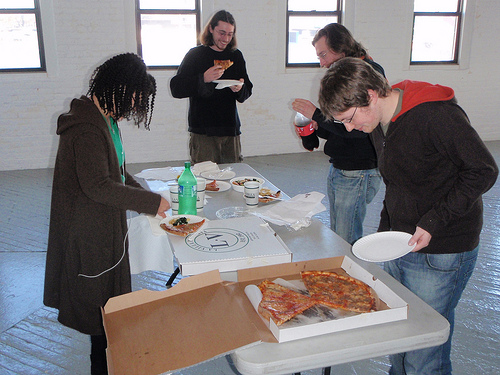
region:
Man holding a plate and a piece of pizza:
[173, 7, 253, 163]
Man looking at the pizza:
[318, 57, 497, 372]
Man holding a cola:
[291, 17, 384, 243]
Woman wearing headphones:
[42, 49, 171, 372]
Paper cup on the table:
[243, 182, 261, 207]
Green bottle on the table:
[177, 160, 198, 215]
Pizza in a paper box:
[256, 269, 376, 326]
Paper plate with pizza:
[161, 215, 205, 235]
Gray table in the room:
[145, 157, 450, 372]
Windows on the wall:
[2, 0, 462, 70]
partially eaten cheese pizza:
[253, 267, 383, 328]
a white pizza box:
[92, 242, 424, 368]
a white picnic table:
[124, 146, 459, 373]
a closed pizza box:
[160, 202, 296, 280]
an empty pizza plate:
[337, 209, 439, 292]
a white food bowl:
[221, 161, 270, 198]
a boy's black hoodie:
[359, 75, 499, 264]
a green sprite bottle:
[176, 152, 215, 234]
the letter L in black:
[207, 235, 234, 252]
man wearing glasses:
[315, 53, 395, 140]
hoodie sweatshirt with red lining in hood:
[376, 75, 498, 260]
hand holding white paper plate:
[348, 218, 438, 269]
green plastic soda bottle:
[172, 156, 201, 224]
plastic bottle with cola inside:
[289, 96, 324, 157]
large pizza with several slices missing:
[187, 250, 416, 365]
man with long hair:
[169, 8, 259, 137]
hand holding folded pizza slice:
[197, 51, 234, 85]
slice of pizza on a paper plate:
[150, 205, 213, 244]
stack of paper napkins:
[192, 159, 221, 178]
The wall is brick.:
[1, 0, 491, 141]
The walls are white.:
[2, 7, 497, 158]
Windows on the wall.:
[1, 2, 487, 76]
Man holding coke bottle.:
[287, 88, 319, 150]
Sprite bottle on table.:
[168, 154, 201, 224]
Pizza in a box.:
[228, 250, 403, 332]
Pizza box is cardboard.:
[90, 252, 409, 374]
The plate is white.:
[350, 223, 417, 265]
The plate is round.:
[350, 221, 422, 266]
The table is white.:
[131, 147, 478, 369]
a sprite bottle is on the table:
[155, 144, 224, 228]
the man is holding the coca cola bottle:
[265, 19, 352, 166]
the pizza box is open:
[200, 260, 432, 360]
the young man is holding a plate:
[348, 220, 448, 277]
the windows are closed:
[2, 8, 478, 87]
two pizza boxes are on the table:
[122, 182, 424, 320]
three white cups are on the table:
[142, 175, 269, 235]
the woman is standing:
[43, 31, 169, 370]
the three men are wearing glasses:
[155, 2, 407, 171]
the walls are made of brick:
[5, 32, 123, 126]